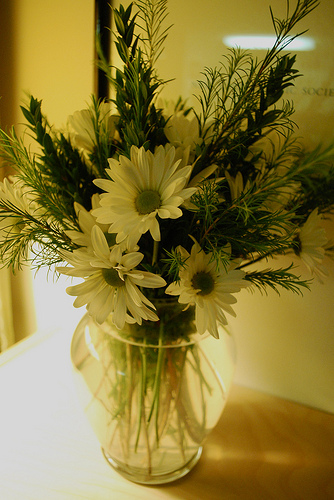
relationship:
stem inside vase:
[147, 314, 165, 423] [68, 286, 237, 485]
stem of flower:
[147, 314, 165, 423] [99, 142, 182, 242]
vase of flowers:
[68, 286, 237, 485] [1, 2, 333, 344]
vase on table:
[68, 286, 237, 485] [4, 315, 331, 499]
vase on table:
[91, 323, 207, 402] [27, 350, 326, 498]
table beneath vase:
[4, 315, 331, 499] [49, 329, 212, 468]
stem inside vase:
[147, 319, 167, 425] [68, 308, 237, 486]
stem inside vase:
[147, 314, 165, 423] [68, 308, 237, 486]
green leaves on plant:
[248, 258, 313, 299] [12, 55, 307, 489]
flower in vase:
[163, 238, 251, 338] [74, 286, 233, 485]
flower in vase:
[88, 140, 201, 249] [74, 286, 233, 485]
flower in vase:
[54, 232, 162, 331] [74, 286, 233, 485]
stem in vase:
[147, 314, 165, 423] [74, 286, 233, 485]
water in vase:
[111, 350, 186, 458] [68, 286, 237, 485]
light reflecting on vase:
[73, 321, 131, 388] [61, 281, 288, 482]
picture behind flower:
[88, 1, 317, 248] [90, 139, 196, 254]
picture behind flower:
[88, 1, 317, 248] [166, 232, 249, 336]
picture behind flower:
[88, 1, 317, 248] [56, 219, 168, 323]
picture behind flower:
[88, 1, 317, 248] [0, 165, 63, 248]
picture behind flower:
[88, 1, 317, 248] [220, 163, 294, 215]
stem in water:
[147, 314, 165, 423] [72, 312, 236, 486]